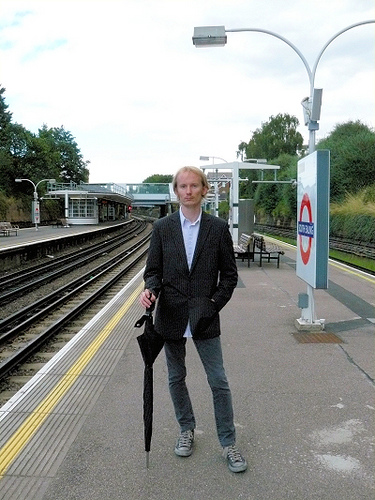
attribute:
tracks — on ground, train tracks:
[1, 214, 164, 400]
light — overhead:
[189, 24, 232, 51]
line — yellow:
[1, 277, 148, 475]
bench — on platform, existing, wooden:
[230, 230, 259, 268]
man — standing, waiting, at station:
[137, 161, 258, 473]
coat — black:
[140, 209, 240, 343]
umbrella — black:
[133, 290, 169, 471]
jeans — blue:
[160, 328, 238, 451]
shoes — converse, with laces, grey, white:
[172, 423, 247, 479]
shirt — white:
[175, 205, 207, 274]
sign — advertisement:
[293, 148, 333, 292]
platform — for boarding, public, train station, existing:
[0, 212, 374, 499]